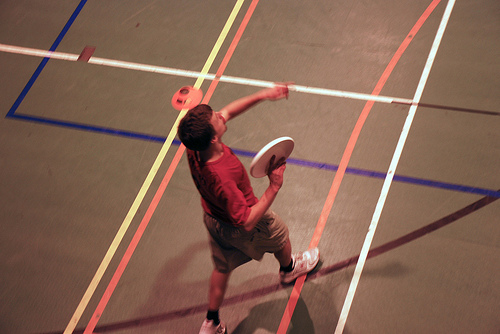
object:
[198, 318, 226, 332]
shoes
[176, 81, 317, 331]
man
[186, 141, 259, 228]
red shirt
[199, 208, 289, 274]
khaki pants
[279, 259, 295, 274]
black sock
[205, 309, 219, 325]
black sock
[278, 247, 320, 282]
shoe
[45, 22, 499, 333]
line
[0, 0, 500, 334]
court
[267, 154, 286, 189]
hand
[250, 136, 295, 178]
frisbee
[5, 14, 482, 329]
floor